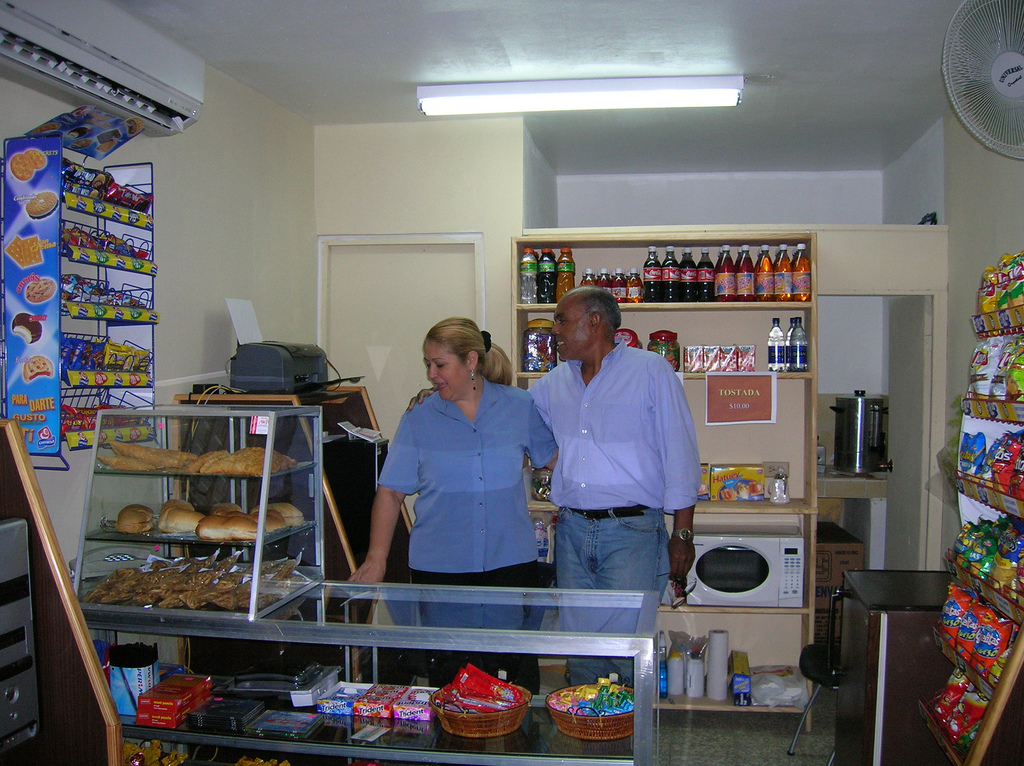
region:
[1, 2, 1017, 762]
the people are standing in the store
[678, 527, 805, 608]
the microwave is white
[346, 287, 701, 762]
the man with his arm around the woman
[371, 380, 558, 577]
the buttoned up shirt is blue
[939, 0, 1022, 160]
the fan is white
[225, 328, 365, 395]
the printer is dark grey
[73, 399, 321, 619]
the food in the glass display case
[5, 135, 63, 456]
the pictures of the snacks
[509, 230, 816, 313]
the bottled drinks on the light colored shelf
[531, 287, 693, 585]
Man in blue button down is standing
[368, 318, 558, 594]
Woman in blue blouse is standing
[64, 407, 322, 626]
Case filled with baked goods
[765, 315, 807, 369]
Bottles of water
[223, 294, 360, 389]
printer is gray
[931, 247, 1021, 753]
Stand full of chips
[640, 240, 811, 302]
Wall of sodas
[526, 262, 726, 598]
man in the store he owns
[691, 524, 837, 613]
microwave in the store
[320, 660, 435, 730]
gum in the display case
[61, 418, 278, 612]
baked items in the display case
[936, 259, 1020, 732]
chips and snacks on the display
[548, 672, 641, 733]
candy in a basket in the display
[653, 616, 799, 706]
cups and wrap on the shelf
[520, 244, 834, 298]
bottled soda on the top shelf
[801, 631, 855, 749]
black stool on the floor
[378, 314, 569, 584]
Woman wearing a blue shirt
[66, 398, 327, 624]
Display case full of breads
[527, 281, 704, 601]
Man in a blue shirt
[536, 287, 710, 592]
Man wearing a wrist watch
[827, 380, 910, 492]
Black and stainless steel coffee maker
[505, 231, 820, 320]
Different colored bottles on a shelf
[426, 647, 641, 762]
Two wicker baskets full of treats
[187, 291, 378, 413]
Small gray printer with paper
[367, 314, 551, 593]
woman standing behind the counter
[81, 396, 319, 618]
display case of baked goods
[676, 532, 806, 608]
white microwave on the shelf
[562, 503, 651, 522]
black belt the man is wearing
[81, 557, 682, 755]
glass case in front of the people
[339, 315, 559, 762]
a woman standing beside a man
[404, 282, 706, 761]
a man standing beside a woman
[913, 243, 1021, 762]
potato chips on a rack against a wall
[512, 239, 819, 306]
soda bottles on a shelf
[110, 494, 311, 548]
bread rolls inside a display case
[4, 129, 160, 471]
snacks on a rack against a wall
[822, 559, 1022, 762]
small refrigerator against a wall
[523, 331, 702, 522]
man wearing a blue shirt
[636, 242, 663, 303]
coke bottle on shelf in store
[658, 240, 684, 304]
coke bottle on shelf in store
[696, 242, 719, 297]
coke bottle on shelf in store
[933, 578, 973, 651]
bag of chips on rack in store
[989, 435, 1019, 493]
bag of chips on rack in store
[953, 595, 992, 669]
bag of chips on rack in store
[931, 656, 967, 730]
bag of chips on rack in store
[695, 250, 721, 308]
a bottle on the shelf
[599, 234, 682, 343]
a bottle on the shelf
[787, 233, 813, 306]
orange colored bottle of soda on shelf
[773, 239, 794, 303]
orange colored bottle of soda on shelf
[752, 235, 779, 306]
orange colored bottle of soda on shelf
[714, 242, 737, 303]
red colored bottle of soda on shelf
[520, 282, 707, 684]
man in a purple colored shirt